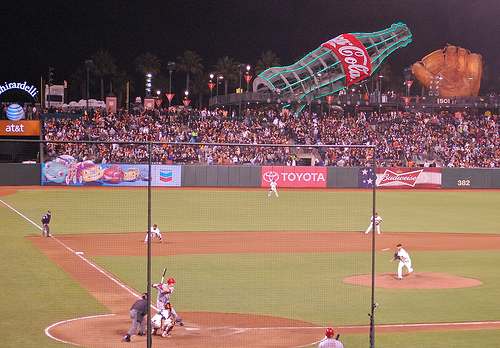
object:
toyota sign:
[262, 166, 324, 185]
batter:
[151, 268, 184, 329]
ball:
[382, 246, 389, 251]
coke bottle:
[253, 22, 412, 117]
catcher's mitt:
[175, 319, 183, 326]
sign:
[1, 120, 40, 140]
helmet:
[168, 278, 176, 284]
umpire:
[126, 290, 148, 340]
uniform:
[125, 303, 147, 337]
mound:
[345, 272, 482, 291]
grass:
[142, 197, 196, 214]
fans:
[87, 116, 123, 144]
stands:
[114, 130, 229, 164]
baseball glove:
[410, 44, 482, 99]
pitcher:
[392, 243, 417, 277]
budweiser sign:
[364, 167, 441, 188]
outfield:
[223, 187, 318, 222]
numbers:
[456, 178, 472, 190]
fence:
[446, 170, 496, 189]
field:
[206, 269, 256, 299]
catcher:
[150, 301, 173, 338]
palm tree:
[135, 49, 161, 84]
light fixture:
[235, 55, 257, 78]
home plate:
[181, 319, 200, 335]